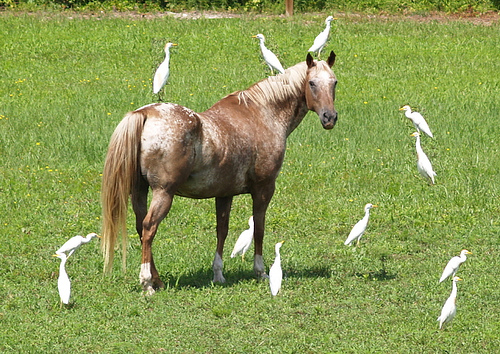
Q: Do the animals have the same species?
A: No, there are both horses and birds.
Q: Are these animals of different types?
A: Yes, they are horses and birds.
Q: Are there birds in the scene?
A: Yes, there is a bird.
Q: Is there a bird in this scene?
A: Yes, there is a bird.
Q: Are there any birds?
A: Yes, there is a bird.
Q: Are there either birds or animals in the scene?
A: Yes, there is a bird.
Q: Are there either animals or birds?
A: Yes, there is a bird.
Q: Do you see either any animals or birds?
A: Yes, there is a bird.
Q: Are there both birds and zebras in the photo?
A: No, there is a bird but no zebras.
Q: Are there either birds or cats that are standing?
A: Yes, the bird is standing.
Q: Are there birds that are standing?
A: Yes, there is a bird that is standing.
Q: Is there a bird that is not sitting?
A: Yes, there is a bird that is standing.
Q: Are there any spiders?
A: No, there are no spiders.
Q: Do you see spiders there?
A: No, there are no spiders.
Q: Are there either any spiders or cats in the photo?
A: No, there are no spiders or cats.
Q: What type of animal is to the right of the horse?
A: The animal is a bird.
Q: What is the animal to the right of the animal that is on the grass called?
A: The animal is a bird.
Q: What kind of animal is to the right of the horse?
A: The animal is a bird.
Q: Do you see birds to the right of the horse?
A: Yes, there is a bird to the right of the horse.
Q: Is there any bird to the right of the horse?
A: Yes, there is a bird to the right of the horse.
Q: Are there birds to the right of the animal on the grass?
A: Yes, there is a bird to the right of the horse.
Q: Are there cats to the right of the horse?
A: No, there is a bird to the right of the horse.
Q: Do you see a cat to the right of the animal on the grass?
A: No, there is a bird to the right of the horse.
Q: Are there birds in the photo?
A: Yes, there is a bird.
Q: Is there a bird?
A: Yes, there is a bird.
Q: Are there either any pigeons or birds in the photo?
A: Yes, there is a bird.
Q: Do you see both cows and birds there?
A: No, there is a bird but no cows.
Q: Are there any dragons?
A: No, there are no dragons.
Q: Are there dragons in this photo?
A: No, there are no dragons.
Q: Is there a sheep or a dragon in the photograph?
A: No, there are no dragons or sheep.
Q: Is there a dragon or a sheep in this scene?
A: No, there are no dragons or sheep.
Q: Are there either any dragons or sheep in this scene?
A: No, there are no dragons or sheep.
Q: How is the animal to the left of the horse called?
A: The animal is a bird.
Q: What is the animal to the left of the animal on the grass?
A: The animal is a bird.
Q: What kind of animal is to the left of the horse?
A: The animal is a bird.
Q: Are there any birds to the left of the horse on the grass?
A: Yes, there is a bird to the left of the horse.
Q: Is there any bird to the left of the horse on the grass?
A: Yes, there is a bird to the left of the horse.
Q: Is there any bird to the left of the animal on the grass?
A: Yes, there is a bird to the left of the horse.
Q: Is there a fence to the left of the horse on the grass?
A: No, there is a bird to the left of the horse.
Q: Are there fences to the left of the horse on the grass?
A: No, there is a bird to the left of the horse.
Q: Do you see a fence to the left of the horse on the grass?
A: No, there is a bird to the left of the horse.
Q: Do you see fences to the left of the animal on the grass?
A: No, there is a bird to the left of the horse.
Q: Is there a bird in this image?
A: Yes, there is a bird.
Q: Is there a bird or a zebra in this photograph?
A: Yes, there is a bird.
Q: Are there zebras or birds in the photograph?
A: Yes, there is a bird.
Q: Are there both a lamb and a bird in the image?
A: No, there is a bird but no lambs.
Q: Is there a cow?
A: No, there are no cows.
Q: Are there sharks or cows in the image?
A: No, there are no cows or sharks.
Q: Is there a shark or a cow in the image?
A: No, there are no cows or sharks.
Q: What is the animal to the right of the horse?
A: The animal is a bird.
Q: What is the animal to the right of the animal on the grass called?
A: The animal is a bird.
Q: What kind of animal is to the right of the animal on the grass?
A: The animal is a bird.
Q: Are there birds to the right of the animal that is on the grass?
A: Yes, there is a bird to the right of the horse.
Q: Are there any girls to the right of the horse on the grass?
A: No, there is a bird to the right of the horse.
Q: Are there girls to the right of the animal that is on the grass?
A: No, there is a bird to the right of the horse.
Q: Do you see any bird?
A: Yes, there is a bird.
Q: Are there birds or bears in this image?
A: Yes, there is a bird.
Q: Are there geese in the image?
A: No, there are no geese.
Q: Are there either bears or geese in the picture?
A: No, there are no geese or bears.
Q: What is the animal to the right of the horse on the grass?
A: The animal is a bird.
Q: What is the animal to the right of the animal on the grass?
A: The animal is a bird.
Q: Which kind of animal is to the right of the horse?
A: The animal is a bird.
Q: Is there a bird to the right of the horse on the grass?
A: Yes, there is a bird to the right of the horse.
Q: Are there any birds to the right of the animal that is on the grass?
A: Yes, there is a bird to the right of the horse.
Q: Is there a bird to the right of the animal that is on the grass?
A: Yes, there is a bird to the right of the horse.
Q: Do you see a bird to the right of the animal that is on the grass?
A: Yes, there is a bird to the right of the horse.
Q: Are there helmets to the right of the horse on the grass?
A: No, there is a bird to the right of the horse.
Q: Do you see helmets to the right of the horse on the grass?
A: No, there is a bird to the right of the horse.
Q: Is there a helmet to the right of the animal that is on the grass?
A: No, there is a bird to the right of the horse.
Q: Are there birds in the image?
A: Yes, there is a bird.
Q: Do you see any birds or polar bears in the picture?
A: Yes, there is a bird.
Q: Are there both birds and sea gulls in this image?
A: No, there is a bird but no seagulls.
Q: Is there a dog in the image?
A: No, there are no dogs.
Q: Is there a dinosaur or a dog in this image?
A: No, there are no dogs or dinosaurs.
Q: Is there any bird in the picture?
A: Yes, there is a bird.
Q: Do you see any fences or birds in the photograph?
A: Yes, there is a bird.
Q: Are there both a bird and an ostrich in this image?
A: No, there is a bird but no ostriches.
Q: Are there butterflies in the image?
A: No, there are no butterflies.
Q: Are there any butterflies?
A: No, there are no butterflies.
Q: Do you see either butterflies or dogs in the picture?
A: No, there are no butterflies or dogs.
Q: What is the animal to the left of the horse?
A: The animal is a bird.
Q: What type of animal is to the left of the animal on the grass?
A: The animal is a bird.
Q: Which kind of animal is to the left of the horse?
A: The animal is a bird.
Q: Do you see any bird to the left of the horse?
A: Yes, there is a bird to the left of the horse.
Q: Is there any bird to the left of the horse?
A: Yes, there is a bird to the left of the horse.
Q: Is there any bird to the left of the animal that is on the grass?
A: Yes, there is a bird to the left of the horse.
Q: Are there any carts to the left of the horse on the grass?
A: No, there is a bird to the left of the horse.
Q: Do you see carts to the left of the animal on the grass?
A: No, there is a bird to the left of the horse.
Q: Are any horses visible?
A: Yes, there is a horse.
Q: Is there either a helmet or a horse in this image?
A: Yes, there is a horse.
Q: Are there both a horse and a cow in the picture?
A: No, there is a horse but no cows.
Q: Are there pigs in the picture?
A: No, there are no pigs.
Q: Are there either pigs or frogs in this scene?
A: No, there are no pigs or frogs.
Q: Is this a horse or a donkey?
A: This is a horse.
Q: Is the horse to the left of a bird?
A: No, the horse is to the right of a bird.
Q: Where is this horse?
A: The horse is on the grass.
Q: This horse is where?
A: The horse is on the grass.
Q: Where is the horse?
A: The horse is on the grass.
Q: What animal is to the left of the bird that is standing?
A: The animal is a horse.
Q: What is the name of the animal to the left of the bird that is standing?
A: The animal is a horse.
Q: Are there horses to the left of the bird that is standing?
A: Yes, there is a horse to the left of the bird.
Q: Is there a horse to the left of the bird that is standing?
A: Yes, there is a horse to the left of the bird.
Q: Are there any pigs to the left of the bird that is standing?
A: No, there is a horse to the left of the bird.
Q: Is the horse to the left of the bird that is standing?
A: Yes, the horse is to the left of the bird.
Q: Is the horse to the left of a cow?
A: No, the horse is to the left of the bird.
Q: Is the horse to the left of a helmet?
A: No, the horse is to the left of a bird.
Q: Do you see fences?
A: No, there are no fences.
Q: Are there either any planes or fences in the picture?
A: No, there are no fences or planes.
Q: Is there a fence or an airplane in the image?
A: No, there are no fences or airplanes.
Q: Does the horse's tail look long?
A: Yes, the tail is long.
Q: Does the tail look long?
A: Yes, the tail is long.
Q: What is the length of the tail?
A: The tail is long.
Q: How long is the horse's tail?
A: The tail is long.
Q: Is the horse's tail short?
A: No, the tail is long.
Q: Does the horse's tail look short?
A: No, the tail is long.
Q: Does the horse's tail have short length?
A: No, the tail is long.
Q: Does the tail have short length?
A: No, the tail is long.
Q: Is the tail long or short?
A: The tail is long.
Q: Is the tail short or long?
A: The tail is long.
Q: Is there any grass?
A: Yes, there is grass.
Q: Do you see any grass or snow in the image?
A: Yes, there is grass.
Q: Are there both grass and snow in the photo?
A: No, there is grass but no snow.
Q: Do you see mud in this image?
A: No, there is no mud.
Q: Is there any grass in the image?
A: Yes, there is grass.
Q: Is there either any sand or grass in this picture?
A: Yes, there is grass.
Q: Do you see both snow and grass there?
A: No, there is grass but no snow.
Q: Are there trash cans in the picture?
A: No, there are no trash cans.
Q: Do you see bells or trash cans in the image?
A: No, there are no trash cans or bells.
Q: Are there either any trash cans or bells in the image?
A: No, there are no trash cans or bells.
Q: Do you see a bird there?
A: Yes, there is a bird.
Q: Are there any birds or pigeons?
A: Yes, there is a bird.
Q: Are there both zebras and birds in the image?
A: No, there is a bird but no zebras.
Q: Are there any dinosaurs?
A: No, there are no dinosaurs.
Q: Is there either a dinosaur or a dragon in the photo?
A: No, there are no dinosaurs or dragons.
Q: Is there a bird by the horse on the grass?
A: Yes, there is a bird by the horse.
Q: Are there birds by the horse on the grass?
A: Yes, there is a bird by the horse.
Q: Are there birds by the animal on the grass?
A: Yes, there is a bird by the horse.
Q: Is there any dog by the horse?
A: No, there is a bird by the horse.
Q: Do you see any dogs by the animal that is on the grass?
A: No, there is a bird by the horse.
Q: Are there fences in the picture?
A: No, there are no fences.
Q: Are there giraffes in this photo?
A: No, there are no giraffes.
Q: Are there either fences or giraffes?
A: No, there are no giraffes or fences.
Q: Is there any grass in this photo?
A: Yes, there is grass.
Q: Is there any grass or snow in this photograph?
A: Yes, there is grass.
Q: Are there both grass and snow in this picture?
A: No, there is grass but no snow.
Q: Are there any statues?
A: No, there are no statues.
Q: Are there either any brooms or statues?
A: No, there are no statues or brooms.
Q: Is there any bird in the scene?
A: Yes, there is a bird.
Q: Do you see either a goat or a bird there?
A: Yes, there is a bird.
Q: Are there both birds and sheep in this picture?
A: No, there is a bird but no sheep.